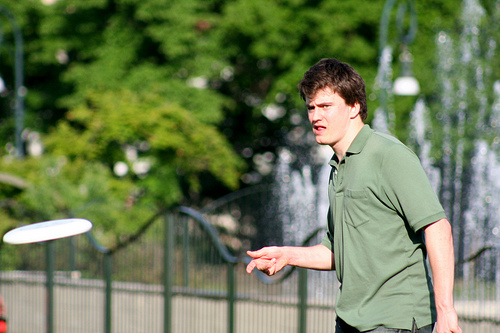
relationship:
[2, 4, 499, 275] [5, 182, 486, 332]
trees behind a fence